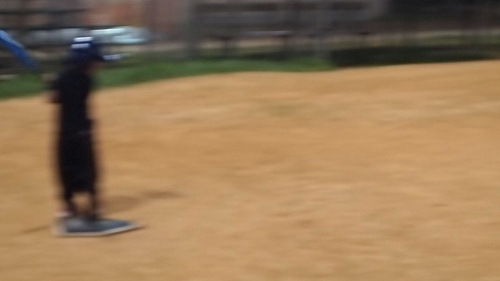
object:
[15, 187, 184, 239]
shadow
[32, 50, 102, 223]
batter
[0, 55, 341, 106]
grass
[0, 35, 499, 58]
baseball field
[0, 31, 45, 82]
bat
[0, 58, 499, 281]
dirt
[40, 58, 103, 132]
shirt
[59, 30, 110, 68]
helmet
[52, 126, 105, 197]
shorts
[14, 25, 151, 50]
cars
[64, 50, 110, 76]
head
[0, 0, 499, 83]
fence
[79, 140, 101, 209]
legs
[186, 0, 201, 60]
pole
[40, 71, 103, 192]
clothing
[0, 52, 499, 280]
field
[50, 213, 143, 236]
base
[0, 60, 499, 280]
ground